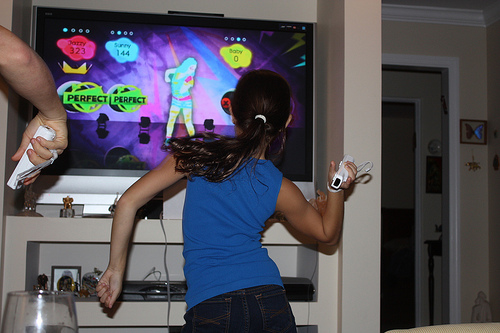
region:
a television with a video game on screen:
[6, 6, 323, 181]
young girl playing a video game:
[110, 95, 375, 322]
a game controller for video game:
[19, 73, 76, 215]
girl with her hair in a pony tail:
[192, 75, 311, 180]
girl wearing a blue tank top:
[178, 145, 294, 331]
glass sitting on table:
[9, 272, 101, 332]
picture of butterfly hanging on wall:
[453, 98, 498, 179]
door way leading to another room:
[384, 67, 466, 329]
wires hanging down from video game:
[151, 208, 186, 331]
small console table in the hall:
[423, 217, 448, 325]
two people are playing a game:
[9, 28, 399, 323]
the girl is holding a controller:
[293, 145, 377, 202]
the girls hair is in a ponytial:
[159, 103, 275, 195]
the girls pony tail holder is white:
[253, 105, 269, 127]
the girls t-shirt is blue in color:
[174, 133, 298, 313]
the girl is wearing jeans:
[171, 275, 311, 331]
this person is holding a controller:
[8, 100, 78, 205]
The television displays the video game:
[29, 5, 320, 203]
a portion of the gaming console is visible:
[164, 180, 189, 223]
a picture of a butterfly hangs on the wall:
[457, 112, 488, 159]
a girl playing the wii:
[72, 47, 362, 331]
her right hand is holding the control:
[324, 150, 379, 197]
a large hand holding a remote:
[1, 116, 64, 191]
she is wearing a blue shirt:
[172, 139, 286, 305]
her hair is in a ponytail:
[162, 66, 297, 190]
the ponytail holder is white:
[251, 114, 270, 124]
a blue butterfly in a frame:
[452, 117, 492, 150]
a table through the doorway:
[422, 230, 452, 318]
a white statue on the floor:
[457, 284, 494, 331]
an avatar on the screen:
[155, 52, 203, 144]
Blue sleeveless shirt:
[172, 141, 294, 315]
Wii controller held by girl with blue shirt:
[321, 148, 373, 197]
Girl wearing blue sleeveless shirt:
[92, 66, 368, 328]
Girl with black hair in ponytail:
[87, 62, 373, 328]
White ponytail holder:
[246, 108, 270, 128]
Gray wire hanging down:
[151, 210, 181, 330]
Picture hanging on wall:
[453, 112, 494, 150]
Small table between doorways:
[416, 221, 448, 328]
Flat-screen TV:
[19, 0, 326, 206]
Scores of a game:
[48, 23, 270, 80]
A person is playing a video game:
[78, 30, 473, 326]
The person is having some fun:
[86, 37, 447, 329]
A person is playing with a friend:
[0, 27, 495, 322]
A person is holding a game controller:
[80, 33, 483, 325]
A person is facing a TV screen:
[71, 12, 497, 319]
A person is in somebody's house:
[78, 16, 483, 321]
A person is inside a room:
[76, 21, 482, 307]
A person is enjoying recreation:
[70, 41, 476, 321]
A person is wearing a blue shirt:
[80, 40, 478, 312]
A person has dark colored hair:
[89, 48, 471, 308]